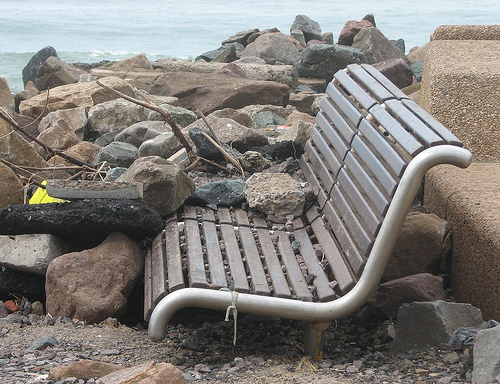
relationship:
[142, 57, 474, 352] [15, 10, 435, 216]
bench on rocks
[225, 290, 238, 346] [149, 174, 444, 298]
rope hanging off bench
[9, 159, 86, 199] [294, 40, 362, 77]
twig stuck in boulder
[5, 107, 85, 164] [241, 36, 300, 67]
twig stuck in boulder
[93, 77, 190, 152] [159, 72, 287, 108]
twig stuck in boulder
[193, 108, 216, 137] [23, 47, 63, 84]
twig stuck in boulder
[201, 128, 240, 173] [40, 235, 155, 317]
twig stuck in boulder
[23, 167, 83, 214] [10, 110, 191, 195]
debris stuck in rocks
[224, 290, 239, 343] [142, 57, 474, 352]
rope tied to bench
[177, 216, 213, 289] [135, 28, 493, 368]
bar on bench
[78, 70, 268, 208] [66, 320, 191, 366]
rocks in dirt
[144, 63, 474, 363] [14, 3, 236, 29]
bench by ocean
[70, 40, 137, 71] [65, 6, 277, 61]
waves on water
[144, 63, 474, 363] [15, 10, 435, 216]
bench under rocks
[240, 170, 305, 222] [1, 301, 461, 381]
rock on ground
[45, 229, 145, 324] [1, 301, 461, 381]
rock on ground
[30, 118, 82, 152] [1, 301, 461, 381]
rock on ground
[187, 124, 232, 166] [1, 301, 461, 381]
rock on ground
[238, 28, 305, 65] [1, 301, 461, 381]
rock on ground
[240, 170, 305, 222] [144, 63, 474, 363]
rock near bench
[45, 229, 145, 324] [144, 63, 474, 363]
rock near bench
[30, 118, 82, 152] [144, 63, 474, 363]
rock near bench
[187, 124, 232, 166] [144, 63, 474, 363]
rock near bench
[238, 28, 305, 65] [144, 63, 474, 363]
rock near bench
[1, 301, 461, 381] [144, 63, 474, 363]
ground near bench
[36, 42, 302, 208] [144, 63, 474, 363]
large rocks on top of bench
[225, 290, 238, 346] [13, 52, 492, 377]
rope on beach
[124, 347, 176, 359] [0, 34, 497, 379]
dirt on ground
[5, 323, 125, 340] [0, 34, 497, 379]
dirt on ground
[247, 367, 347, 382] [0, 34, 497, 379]
dirt on ground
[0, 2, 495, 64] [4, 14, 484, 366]
sea water in rocks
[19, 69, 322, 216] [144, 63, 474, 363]
several rocks are on a bench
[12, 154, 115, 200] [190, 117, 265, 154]
twigs are on a rock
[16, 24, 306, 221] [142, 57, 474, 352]
rocks are on top of bench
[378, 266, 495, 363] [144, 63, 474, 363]
rocks are behind bench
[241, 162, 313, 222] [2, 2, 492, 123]
rock along shoreline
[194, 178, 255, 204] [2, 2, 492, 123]
rock along shoreline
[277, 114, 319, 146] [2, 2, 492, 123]
rock along shoreline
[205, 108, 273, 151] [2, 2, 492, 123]
rock along shoreline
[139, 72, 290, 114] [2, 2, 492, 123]
rock along shoreline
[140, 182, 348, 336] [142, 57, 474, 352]
seat on bench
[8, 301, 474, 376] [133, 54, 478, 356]
gravel underneath park bench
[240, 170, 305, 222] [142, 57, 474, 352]
rock on bench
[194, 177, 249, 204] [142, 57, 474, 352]
rock on bench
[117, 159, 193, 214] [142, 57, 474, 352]
rock on bench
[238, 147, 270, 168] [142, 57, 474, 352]
rock on bench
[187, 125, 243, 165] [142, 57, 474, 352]
rock on bench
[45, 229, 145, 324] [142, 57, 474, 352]
rock if front of bench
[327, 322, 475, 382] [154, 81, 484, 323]
rocks behind bench